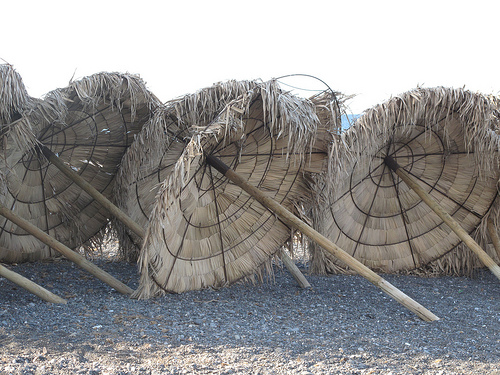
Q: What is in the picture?
A: Umbrellas.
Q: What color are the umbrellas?
A: Gray.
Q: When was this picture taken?
A: During the day.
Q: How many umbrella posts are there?
A: 6.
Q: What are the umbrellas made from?
A: Straw.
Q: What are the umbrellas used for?
A: Shade.